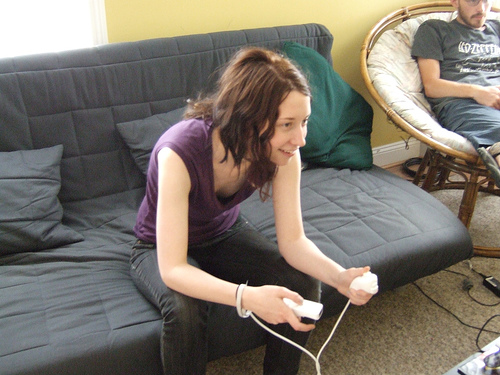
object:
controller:
[348, 270, 381, 298]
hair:
[180, 45, 315, 203]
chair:
[359, 0, 500, 262]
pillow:
[0, 143, 87, 257]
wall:
[105, 0, 418, 151]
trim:
[371, 137, 447, 169]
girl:
[122, 42, 381, 375]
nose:
[288, 123, 307, 148]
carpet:
[206, 163, 500, 375]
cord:
[245, 297, 354, 373]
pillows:
[275, 39, 374, 173]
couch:
[1, 20, 487, 373]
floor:
[203, 157, 500, 375]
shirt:
[129, 113, 273, 246]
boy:
[409, 0, 500, 173]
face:
[256, 90, 313, 167]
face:
[456, 0, 494, 29]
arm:
[410, 18, 479, 100]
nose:
[475, 1, 485, 13]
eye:
[278, 120, 293, 129]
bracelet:
[234, 281, 253, 320]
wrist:
[228, 279, 253, 312]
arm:
[154, 138, 250, 309]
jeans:
[126, 209, 323, 375]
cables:
[411, 280, 500, 336]